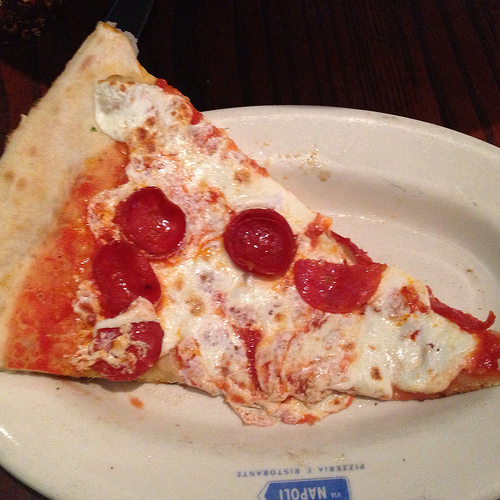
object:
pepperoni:
[223, 208, 298, 282]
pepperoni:
[293, 258, 384, 312]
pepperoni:
[426, 284, 496, 334]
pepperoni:
[113, 185, 187, 257]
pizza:
[1, 20, 500, 428]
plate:
[0, 105, 500, 499]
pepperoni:
[92, 240, 160, 318]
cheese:
[229, 392, 353, 426]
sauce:
[471, 332, 499, 376]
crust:
[1, 16, 152, 376]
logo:
[264, 477, 349, 498]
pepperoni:
[89, 320, 164, 381]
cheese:
[86, 79, 480, 423]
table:
[134, 0, 499, 150]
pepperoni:
[330, 231, 372, 266]